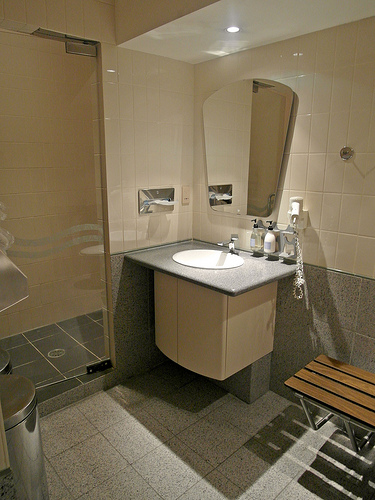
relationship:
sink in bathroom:
[172, 249, 245, 271] [1, 0, 374, 499]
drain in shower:
[47, 346, 67, 360] [0, 29, 110, 389]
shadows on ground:
[103, 358, 374, 499] [40, 361, 374, 499]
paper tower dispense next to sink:
[138, 188, 177, 215] [172, 249, 245, 271]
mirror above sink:
[201, 78, 295, 218] [172, 249, 245, 271]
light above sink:
[227, 25, 240, 35] [172, 249, 245, 271]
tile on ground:
[39, 360, 373, 498] [40, 361, 374, 499]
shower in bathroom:
[0, 29, 110, 389] [1, 0, 374, 499]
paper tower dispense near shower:
[138, 188, 177, 215] [0, 29, 110, 389]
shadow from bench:
[243, 405, 374, 498] [283, 353, 374, 430]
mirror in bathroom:
[201, 78, 295, 218] [1, 0, 374, 499]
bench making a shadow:
[283, 353, 374, 430] [243, 405, 374, 498]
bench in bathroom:
[283, 353, 374, 430] [1, 0, 374, 499]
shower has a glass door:
[0, 29, 110, 389] [0, 32, 110, 389]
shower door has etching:
[0, 32, 110, 389] [1, 196, 105, 258]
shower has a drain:
[0, 29, 110, 389] [47, 346, 67, 360]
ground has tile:
[40, 361, 374, 499] [39, 360, 373, 498]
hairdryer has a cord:
[286, 196, 311, 310] [291, 224, 305, 299]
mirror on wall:
[201, 78, 295, 218] [193, 15, 373, 444]